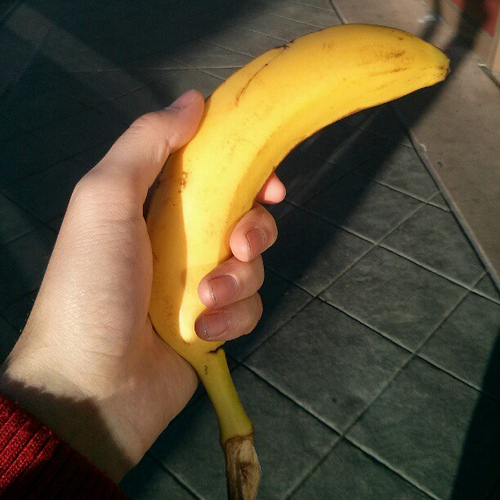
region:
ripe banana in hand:
[128, 15, 457, 379]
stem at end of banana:
[211, 416, 263, 498]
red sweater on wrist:
[4, 408, 84, 488]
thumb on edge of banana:
[129, 79, 207, 168]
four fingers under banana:
[186, 170, 291, 348]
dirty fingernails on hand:
[195, 275, 219, 343]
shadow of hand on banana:
[130, 192, 192, 293]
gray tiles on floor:
[322, 317, 438, 424]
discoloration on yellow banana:
[261, 37, 295, 69]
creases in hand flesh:
[91, 225, 138, 330]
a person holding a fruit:
[51, 13, 478, 463]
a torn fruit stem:
[195, 413, 285, 490]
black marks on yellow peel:
[204, 30, 342, 89]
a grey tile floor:
[249, 253, 445, 475]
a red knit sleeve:
[0, 393, 135, 493]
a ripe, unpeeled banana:
[161, 17, 476, 478]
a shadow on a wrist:
[9, 361, 146, 459]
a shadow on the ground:
[257, 0, 477, 270]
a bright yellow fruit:
[146, 17, 465, 468]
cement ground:
[422, 50, 494, 267]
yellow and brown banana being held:
[156, 35, 463, 457]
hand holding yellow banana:
[19, 53, 316, 445]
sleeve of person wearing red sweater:
[10, 408, 118, 496]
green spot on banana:
[195, 363, 263, 486]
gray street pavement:
[31, 12, 233, 79]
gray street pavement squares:
[263, 317, 451, 462]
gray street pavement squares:
[327, 210, 472, 330]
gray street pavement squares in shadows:
[119, 11, 299, 40]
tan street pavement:
[459, 51, 496, 199]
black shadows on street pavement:
[422, 6, 479, 43]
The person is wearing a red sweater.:
[1, 396, 138, 496]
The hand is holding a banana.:
[69, 80, 361, 370]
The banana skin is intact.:
[349, 9, 462, 109]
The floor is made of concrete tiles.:
[354, 202, 492, 358]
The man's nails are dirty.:
[190, 256, 271, 346]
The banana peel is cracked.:
[194, 335, 251, 372]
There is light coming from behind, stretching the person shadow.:
[227, 1, 497, 181]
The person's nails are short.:
[181, 247, 278, 354]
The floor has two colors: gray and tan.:
[346, 218, 498, 355]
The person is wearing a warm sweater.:
[0, 376, 127, 498]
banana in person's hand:
[32, 16, 438, 389]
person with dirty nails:
[188, 187, 321, 383]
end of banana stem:
[198, 401, 272, 497]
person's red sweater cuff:
[1, 345, 122, 497]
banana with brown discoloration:
[215, 31, 462, 118]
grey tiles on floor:
[316, 297, 448, 484]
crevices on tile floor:
[420, 161, 472, 234]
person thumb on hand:
[91, 47, 204, 292]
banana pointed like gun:
[230, 12, 483, 180]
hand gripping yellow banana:
[40, 120, 303, 481]